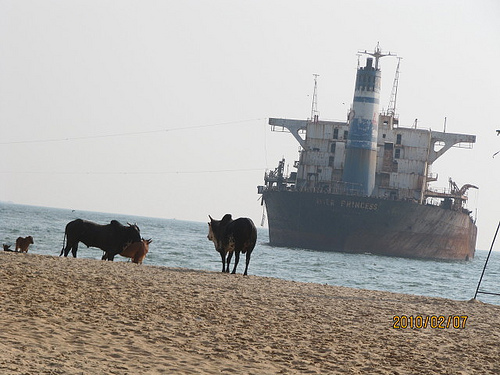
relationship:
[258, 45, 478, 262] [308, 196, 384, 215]
ship has name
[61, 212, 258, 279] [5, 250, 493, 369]
cattle on beach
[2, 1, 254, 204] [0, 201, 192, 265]
sky meets water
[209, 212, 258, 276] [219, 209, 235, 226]
bull has hump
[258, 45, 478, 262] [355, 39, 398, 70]
ship has antenna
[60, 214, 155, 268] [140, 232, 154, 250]
bull has horns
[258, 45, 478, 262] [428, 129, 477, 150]
ship has railing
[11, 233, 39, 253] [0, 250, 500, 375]
animal on beach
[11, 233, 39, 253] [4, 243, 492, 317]
animal near ocean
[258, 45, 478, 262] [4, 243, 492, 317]
ship on ocean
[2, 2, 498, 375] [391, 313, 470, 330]
picture has date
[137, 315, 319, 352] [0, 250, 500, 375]
sand on beach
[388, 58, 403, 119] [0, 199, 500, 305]
rig on ocean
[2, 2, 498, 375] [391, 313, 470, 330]
photo has stamp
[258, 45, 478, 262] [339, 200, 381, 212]
ship says princess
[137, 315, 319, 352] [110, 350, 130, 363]
sand has footprints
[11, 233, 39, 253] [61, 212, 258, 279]
animal in group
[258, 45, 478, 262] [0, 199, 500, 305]
ship in ocean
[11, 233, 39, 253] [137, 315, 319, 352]
cow in sand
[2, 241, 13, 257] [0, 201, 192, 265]
cow by water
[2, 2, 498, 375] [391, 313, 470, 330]
photo has date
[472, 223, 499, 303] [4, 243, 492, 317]
something by ocean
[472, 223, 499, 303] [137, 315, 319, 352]
pole on sand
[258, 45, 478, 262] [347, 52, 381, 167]
boat has pipe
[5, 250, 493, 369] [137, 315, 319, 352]
beach has sand